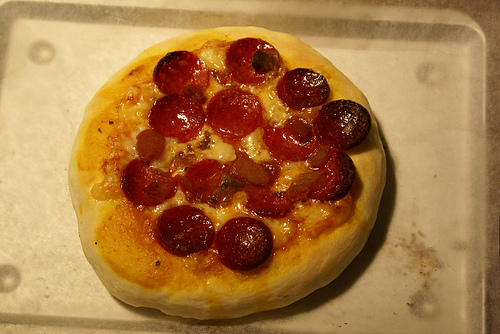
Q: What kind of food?
A: Pizza.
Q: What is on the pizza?
A: Pepperoni.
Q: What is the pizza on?
A: A tray.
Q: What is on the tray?
A: Pizza.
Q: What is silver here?
A: The tray.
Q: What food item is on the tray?
A: Pizza.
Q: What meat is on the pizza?
A: Pepperoni.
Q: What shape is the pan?
A: Rectangular.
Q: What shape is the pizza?
A: Round.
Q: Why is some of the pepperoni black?
A: It is burned.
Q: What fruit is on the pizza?
A: Pineapple.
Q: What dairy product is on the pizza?
A: Cheese.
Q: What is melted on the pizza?
A: Cheese.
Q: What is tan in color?
A: The crust.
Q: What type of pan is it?
A: The metal.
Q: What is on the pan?
A: Pizza.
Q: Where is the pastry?
A: In the tray.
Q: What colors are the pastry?
A: Red and yellow.